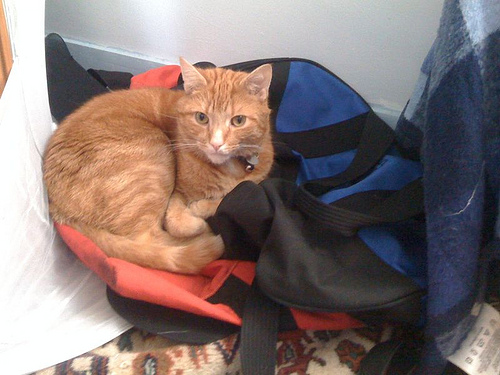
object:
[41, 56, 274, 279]
cat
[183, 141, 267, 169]
neck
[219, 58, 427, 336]
bag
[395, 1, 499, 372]
blanket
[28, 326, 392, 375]
rug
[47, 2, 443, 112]
wall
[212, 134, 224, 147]
nose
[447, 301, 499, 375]
tag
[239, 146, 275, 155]
whisker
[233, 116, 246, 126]
eye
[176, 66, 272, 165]
head